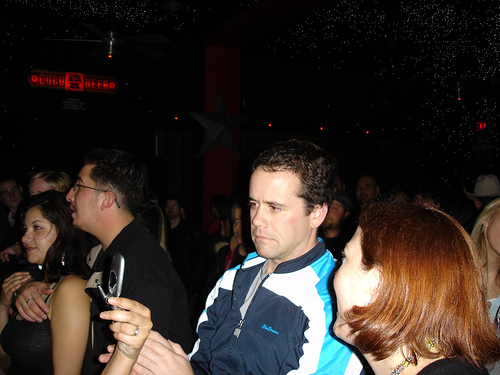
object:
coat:
[186, 235, 365, 373]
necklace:
[383, 340, 437, 374]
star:
[171, 115, 179, 120]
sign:
[26, 70, 117, 92]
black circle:
[105, 269, 119, 291]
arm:
[45, 274, 96, 374]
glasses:
[72, 178, 121, 208]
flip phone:
[95, 254, 123, 325]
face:
[247, 164, 310, 264]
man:
[65, 161, 195, 375]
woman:
[327, 195, 500, 374]